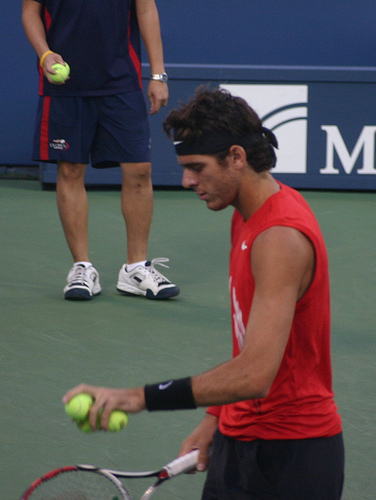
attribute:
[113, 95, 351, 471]
man — playing, wearing, holding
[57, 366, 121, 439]
balls — yellow, bright, tennis, four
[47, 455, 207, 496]
racket — white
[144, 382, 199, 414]
wristband — black, nike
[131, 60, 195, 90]
watch — silver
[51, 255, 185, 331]
sneakers — blue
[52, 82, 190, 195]
shorts — blue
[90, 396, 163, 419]
hand — full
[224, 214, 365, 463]
shirt — sleeveless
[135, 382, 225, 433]
armband — black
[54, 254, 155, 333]
shoes — white, blue, black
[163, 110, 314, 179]
headband — black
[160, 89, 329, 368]
player — male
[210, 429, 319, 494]
shorts — black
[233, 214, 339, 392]
tank top — red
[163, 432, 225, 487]
handle — white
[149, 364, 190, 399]
logo — nike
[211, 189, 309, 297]
top — red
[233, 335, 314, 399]
vest — red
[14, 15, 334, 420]
game — tennis